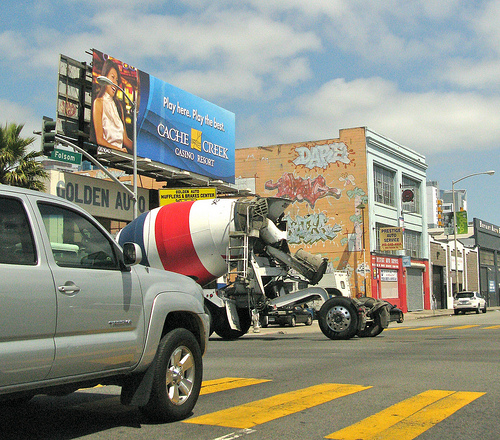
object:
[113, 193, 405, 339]
concrete mixer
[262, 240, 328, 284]
chute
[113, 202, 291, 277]
mixer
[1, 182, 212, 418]
truck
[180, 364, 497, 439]
crosswalk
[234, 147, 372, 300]
wall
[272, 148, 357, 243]
graffiti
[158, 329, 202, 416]
tire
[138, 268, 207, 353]
front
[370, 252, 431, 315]
storefront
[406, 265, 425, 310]
rollup door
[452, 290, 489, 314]
car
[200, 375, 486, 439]
yellow lines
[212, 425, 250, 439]
line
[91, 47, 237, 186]
billboard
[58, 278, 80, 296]
handle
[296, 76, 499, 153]
clouds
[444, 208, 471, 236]
sign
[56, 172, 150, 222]
sign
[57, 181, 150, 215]
writing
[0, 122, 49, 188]
tree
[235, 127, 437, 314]
building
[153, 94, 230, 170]
writing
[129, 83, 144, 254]
pole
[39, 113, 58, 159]
stoplight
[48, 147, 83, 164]
sign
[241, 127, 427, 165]
roof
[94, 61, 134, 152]
woman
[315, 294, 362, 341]
wheels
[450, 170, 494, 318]
street light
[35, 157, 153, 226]
building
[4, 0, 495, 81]
sky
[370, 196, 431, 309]
wall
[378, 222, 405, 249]
sign